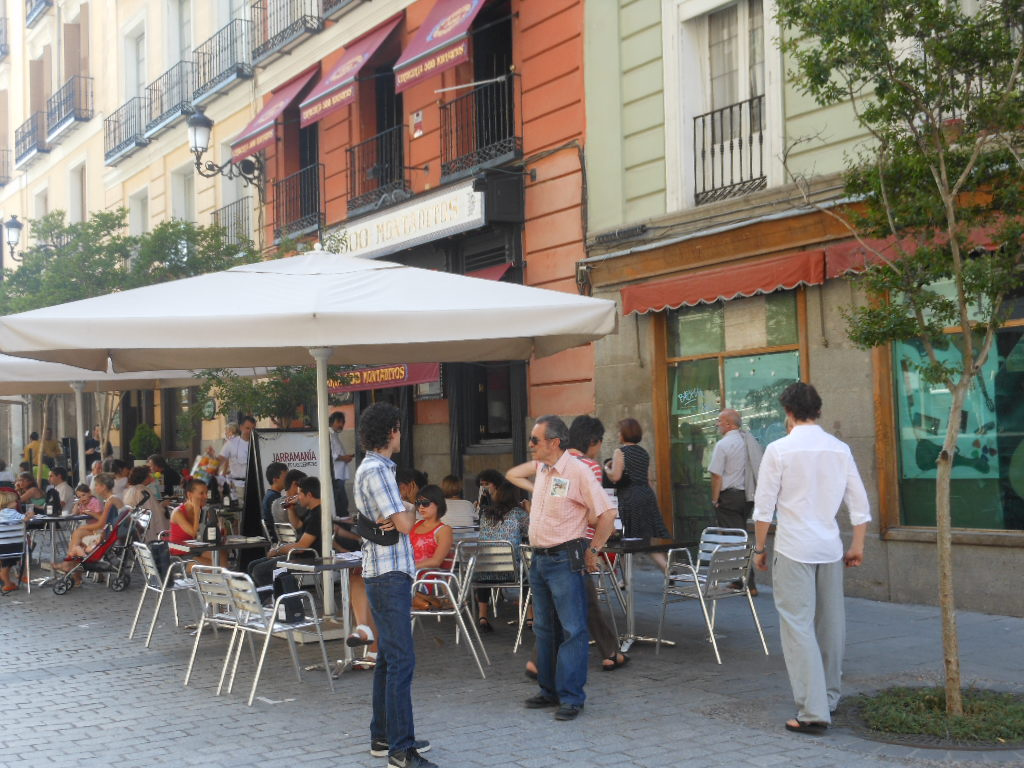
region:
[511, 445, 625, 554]
man is wearing shirt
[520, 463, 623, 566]
shirt is pink in color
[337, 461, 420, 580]
woman is wearing shirt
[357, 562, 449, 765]
woman is wearing jeans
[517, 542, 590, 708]
man is wearing jeans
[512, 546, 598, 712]
jeans are blue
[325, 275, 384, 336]
the umbrella is white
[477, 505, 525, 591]
the lady is sitting in the chair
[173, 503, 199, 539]
the ladys shirt is red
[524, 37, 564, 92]
the building is reddish brown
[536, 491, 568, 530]
the mans shirt is light pink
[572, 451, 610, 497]
the persons shit has stripes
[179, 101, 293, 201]
the light is attached to the building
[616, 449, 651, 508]
the dress is black with white dots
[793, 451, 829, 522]
the mans shirt is white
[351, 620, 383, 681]
the sandles are white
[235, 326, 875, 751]
people are standing around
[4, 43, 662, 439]
the umbrella is open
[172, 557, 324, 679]
the chaIRS ARE SILVER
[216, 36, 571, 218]
the building is rusty orange colored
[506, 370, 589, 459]
the man is wearing shades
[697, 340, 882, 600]
man is wearing a white shirt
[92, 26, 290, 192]
the balconies are black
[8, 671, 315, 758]
the ground is made of bricks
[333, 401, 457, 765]
man standing on sidewalk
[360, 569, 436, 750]
blue jeans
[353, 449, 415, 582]
white and blue checked shirt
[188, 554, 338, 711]
two silver sidewalk chairs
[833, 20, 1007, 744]
tree with green leaves & thin branches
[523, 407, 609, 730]
man in sun glasses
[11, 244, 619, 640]
large white patio umbrella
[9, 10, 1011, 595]
city buildings frontispieces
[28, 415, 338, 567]
group of people sitting at sidewalk cafe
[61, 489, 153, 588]
baby stroller on sidewalk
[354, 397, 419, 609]
a man wearing checkered shirt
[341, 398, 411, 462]
a man with curly hair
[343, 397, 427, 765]
a man wearing blue denim jeans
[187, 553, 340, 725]
steel chairs for outdoors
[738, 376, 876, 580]
a man wearing a white shirt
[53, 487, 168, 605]
a baby's stroller on the street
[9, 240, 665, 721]
a big white tent type umbrella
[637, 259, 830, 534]
green glass window pane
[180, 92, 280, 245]
an old light lamp post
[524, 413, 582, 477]
a man wearing sunglasses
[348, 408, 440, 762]
the man is standing still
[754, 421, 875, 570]
the man is wearing a shirt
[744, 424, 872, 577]
the shirt is white in color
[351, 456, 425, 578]
the man is wearing a plaid shirt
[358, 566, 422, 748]
the man is wearing blue jeans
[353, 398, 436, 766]
young man wearing dark blue jeans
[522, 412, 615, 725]
man in a light colored shirt and blue jeans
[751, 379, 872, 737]
man in a white shirt and light gray pants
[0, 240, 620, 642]
large umbrella the people are sitting under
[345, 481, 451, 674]
a woman in a red dress sitting under the umbrella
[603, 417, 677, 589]
woman in a black dress walking on the street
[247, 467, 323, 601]
young man drinking from a glass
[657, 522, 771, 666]
empty chair at the table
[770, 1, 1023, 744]
a tree growing in the middle of the sidewalk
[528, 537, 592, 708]
blue jeans the man is wearing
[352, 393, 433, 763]
a man standing on sidewalk